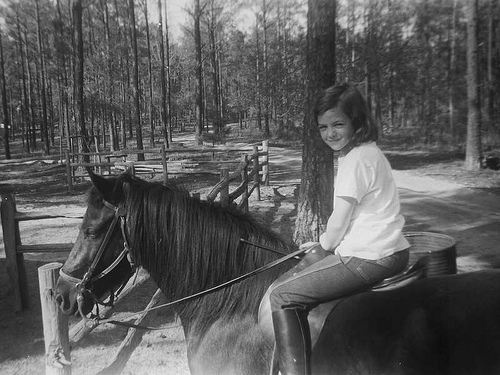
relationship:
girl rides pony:
[261, 77, 419, 374] [44, 157, 499, 374]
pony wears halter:
[44, 157, 499, 374] [50, 189, 148, 325]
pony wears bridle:
[44, 157, 499, 374] [48, 160, 157, 324]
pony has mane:
[44, 157, 499, 374] [75, 166, 305, 343]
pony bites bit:
[44, 157, 499, 374] [65, 296, 101, 328]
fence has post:
[1, 136, 274, 375] [260, 138, 271, 188]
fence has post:
[1, 136, 274, 375] [250, 144, 265, 202]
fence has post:
[1, 136, 274, 375] [238, 150, 252, 215]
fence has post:
[1, 136, 274, 375] [219, 166, 232, 205]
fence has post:
[1, 136, 274, 375] [32, 257, 78, 375]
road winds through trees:
[170, 117, 500, 375] [2, 1, 500, 177]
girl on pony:
[261, 77, 419, 374] [44, 157, 499, 374]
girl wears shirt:
[261, 77, 419, 374] [316, 139, 415, 262]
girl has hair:
[261, 77, 419, 374] [311, 79, 380, 151]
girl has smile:
[261, 77, 419, 374] [326, 136, 345, 145]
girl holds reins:
[261, 77, 419, 374] [71, 236, 324, 338]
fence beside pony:
[1, 136, 274, 375] [44, 157, 499, 374]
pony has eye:
[44, 157, 499, 374] [84, 225, 104, 242]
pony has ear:
[44, 157, 499, 374] [83, 163, 113, 198]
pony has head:
[44, 157, 499, 374] [47, 161, 140, 326]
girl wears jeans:
[261, 77, 419, 374] [266, 236, 422, 311]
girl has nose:
[261, 77, 419, 374] [327, 123, 337, 139]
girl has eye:
[261, 77, 419, 374] [316, 120, 329, 134]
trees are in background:
[2, 1, 500, 177] [1, 1, 500, 258]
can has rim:
[401, 228, 457, 273] [401, 228, 457, 254]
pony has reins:
[44, 157, 499, 374] [71, 236, 324, 338]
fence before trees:
[1, 136, 274, 375] [2, 1, 500, 177]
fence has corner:
[1, 136, 274, 375] [214, 136, 275, 202]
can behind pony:
[401, 228, 457, 273] [44, 157, 499, 374]